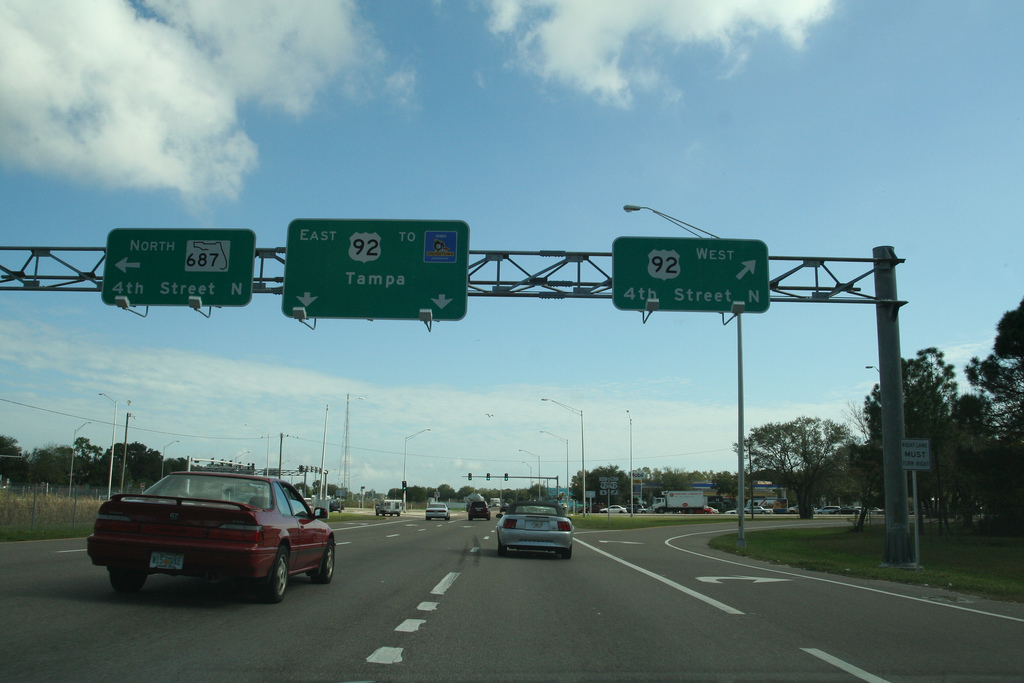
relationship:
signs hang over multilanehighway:
[83, 216, 789, 328] [0, 480, 1024, 683]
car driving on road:
[99, 458, 333, 605] [2, 528, 756, 680]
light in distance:
[498, 468, 515, 482] [395, 433, 629, 533]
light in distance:
[463, 471, 473, 482] [395, 433, 629, 533]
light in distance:
[479, 465, 493, 482] [395, 433, 629, 533]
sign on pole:
[901, 434, 930, 473] [902, 467, 929, 556]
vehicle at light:
[776, 490, 869, 519] [292, 459, 331, 476]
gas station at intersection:
[637, 474, 777, 500] [333, 490, 594, 520]